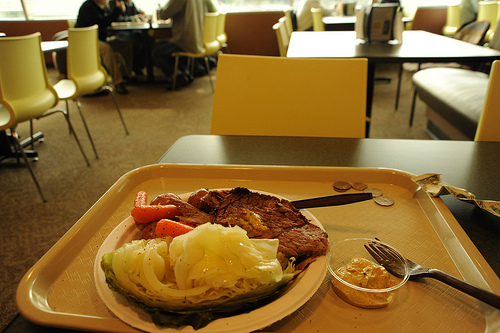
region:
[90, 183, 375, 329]
A PLATE OF FOOD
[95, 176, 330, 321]
CORNED BEEF AND CABBAGE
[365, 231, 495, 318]
A PLASTIC FORK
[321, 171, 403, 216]
CHANGE ON A TRAY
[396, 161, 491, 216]
A DOLLAR ON THE TABLE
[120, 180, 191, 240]
THREE CARROTS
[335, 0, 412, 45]
A NAPKIN HOLDER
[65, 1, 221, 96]
PEOPLE SITTING AT A TABLE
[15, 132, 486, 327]
A PLATE OF FOOD ON A TRAY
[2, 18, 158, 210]
TWO PLASTIC CHAIRS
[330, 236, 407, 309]
a plastic cup of sauce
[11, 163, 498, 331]
a yellow dining tray on the table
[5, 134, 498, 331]
a wooden table in a restaurant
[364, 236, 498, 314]
a fork on the tray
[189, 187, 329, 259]
a steak on the plate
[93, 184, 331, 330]
a paper plate on the tray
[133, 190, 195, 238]
several carrots on the plate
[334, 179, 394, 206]
some coins on the tray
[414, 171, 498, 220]
a dollar bill on the table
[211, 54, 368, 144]
a yellow chair next to the table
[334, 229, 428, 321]
a small clear cup with sauce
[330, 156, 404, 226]
a couple of coins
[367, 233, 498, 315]
a black plastic fork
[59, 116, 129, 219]
a brown colored rug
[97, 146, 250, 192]
a yellow mustard tray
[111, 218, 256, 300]
a pile of sauteed onions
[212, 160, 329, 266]
a brown grilled piece of steak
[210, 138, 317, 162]
a brown table top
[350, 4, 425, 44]
black napkin holder on the table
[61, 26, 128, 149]
yellow and silver dining chair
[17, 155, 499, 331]
tray of food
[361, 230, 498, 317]
black plastic fork on a tray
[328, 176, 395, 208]
change on a tray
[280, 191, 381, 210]
black plastic utinsil on a plate of food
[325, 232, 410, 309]
small clear plastic container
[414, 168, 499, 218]
wrinkled up one dollar bill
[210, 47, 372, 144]
empty chair across the table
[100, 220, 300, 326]
large serving of cooked cabbage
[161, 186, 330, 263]
meat on a paper plate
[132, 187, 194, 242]
three small cooked carrots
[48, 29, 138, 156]
yellow and metal chair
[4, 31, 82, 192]
yellow and metal chair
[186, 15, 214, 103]
yellow and metal chair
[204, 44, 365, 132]
yellow and metal chair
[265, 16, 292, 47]
yellow and metal chair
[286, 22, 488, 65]
brown wooden table in restaurant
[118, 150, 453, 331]
gold tray filled with food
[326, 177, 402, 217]
change on yellow tray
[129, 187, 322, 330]
food on yellow tray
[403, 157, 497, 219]
green and white dollar bill